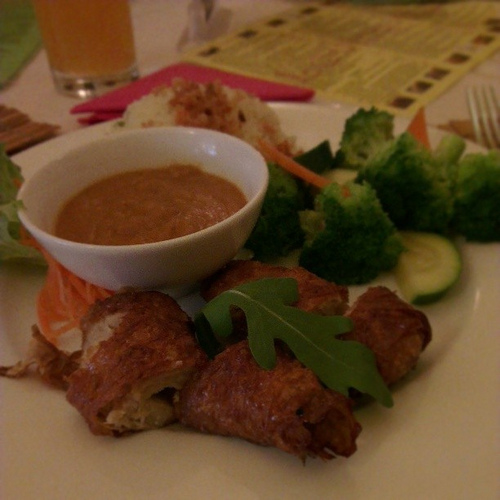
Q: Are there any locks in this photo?
A: No, there are no locks.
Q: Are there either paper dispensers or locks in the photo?
A: No, there are no locks or paper dispensers.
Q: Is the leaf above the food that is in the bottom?
A: Yes, the leaf is above the food.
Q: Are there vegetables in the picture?
A: Yes, there are vegetables.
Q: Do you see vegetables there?
A: Yes, there are vegetables.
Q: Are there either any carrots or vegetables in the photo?
A: Yes, there are vegetables.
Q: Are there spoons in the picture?
A: No, there are no spoons.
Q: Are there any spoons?
A: No, there are no spoons.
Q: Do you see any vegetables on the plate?
A: Yes, there are vegetables on the plate.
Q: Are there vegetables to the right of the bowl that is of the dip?
A: Yes, there are vegetables to the right of the bowl.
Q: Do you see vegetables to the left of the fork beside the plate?
A: Yes, there are vegetables to the left of the fork.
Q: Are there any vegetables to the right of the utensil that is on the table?
A: No, the vegetables are to the left of the fork.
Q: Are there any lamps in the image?
A: No, there are no lamps.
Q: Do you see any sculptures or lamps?
A: No, there are no lamps or sculptures.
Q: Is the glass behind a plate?
A: Yes, the glass is behind a plate.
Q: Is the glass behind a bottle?
A: No, the glass is behind a plate.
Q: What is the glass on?
A: The glass is on the table.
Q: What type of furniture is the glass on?
A: The glass is on the table.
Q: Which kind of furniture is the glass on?
A: The glass is on the table.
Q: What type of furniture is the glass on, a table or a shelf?
A: The glass is on a table.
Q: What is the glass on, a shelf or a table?
A: The glass is on a table.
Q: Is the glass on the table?
A: Yes, the glass is on the table.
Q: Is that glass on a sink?
A: No, the glass is on the table.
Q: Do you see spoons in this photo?
A: No, there are no spoons.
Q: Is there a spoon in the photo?
A: No, there are no spoons.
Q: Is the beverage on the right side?
A: No, the beverage is on the left of the image.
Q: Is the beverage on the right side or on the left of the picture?
A: The beverage is on the left of the image.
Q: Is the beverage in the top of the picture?
A: Yes, the beverage is in the top of the image.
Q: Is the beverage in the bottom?
A: No, the beverage is in the top of the image.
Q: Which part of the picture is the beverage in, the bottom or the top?
A: The beverage is in the top of the image.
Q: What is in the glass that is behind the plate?
A: The beverage is in the glass.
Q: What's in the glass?
A: The beverage is in the glass.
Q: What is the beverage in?
A: The beverage is in the glass.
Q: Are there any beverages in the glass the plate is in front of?
A: Yes, there is a beverage in the glass.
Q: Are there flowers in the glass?
A: No, there is a beverage in the glass.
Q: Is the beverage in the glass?
A: Yes, the beverage is in the glass.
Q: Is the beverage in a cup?
A: No, the beverage is in the glass.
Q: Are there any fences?
A: No, there are no fences.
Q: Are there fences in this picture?
A: No, there are no fences.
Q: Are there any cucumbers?
A: Yes, there is a cucumber.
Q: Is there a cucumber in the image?
A: Yes, there is a cucumber.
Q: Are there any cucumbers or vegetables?
A: Yes, there is a cucumber.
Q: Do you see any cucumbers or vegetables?
A: Yes, there is a cucumber.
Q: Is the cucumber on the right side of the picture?
A: Yes, the cucumber is on the right of the image.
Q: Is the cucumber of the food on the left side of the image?
A: No, the cucumber is on the right of the image.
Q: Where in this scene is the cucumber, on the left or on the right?
A: The cucumber is on the right of the image.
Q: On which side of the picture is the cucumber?
A: The cucumber is on the right of the image.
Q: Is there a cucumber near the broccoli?
A: Yes, there is a cucumber near the broccoli.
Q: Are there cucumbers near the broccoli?
A: Yes, there is a cucumber near the broccoli.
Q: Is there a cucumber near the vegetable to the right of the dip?
A: Yes, there is a cucumber near the broccoli.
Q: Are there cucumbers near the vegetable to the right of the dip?
A: Yes, there is a cucumber near the broccoli.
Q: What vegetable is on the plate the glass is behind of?
A: The vegetable is a cucumber.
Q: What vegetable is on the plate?
A: The vegetable is a cucumber.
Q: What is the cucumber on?
A: The cucumber is on the plate.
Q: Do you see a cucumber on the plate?
A: Yes, there is a cucumber on the plate.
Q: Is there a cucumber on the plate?
A: Yes, there is a cucumber on the plate.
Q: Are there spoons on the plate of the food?
A: No, there is a cucumber on the plate.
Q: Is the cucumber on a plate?
A: Yes, the cucumber is on a plate.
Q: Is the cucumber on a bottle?
A: No, the cucumber is on a plate.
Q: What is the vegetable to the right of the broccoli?
A: The vegetable is a cucumber.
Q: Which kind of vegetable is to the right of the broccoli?
A: The vegetable is a cucumber.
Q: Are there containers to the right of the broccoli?
A: No, there is a cucumber to the right of the broccoli.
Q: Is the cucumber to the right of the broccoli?
A: Yes, the cucumber is to the right of the broccoli.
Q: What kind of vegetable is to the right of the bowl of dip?
A: The vegetable is a cucumber.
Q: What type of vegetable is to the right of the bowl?
A: The vegetable is a cucumber.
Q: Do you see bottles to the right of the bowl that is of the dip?
A: No, there is a cucumber to the right of the bowl.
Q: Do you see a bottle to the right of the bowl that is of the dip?
A: No, there is a cucumber to the right of the bowl.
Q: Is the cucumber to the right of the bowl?
A: Yes, the cucumber is to the right of the bowl.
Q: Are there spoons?
A: No, there are no spoons.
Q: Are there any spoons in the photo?
A: No, there are no spoons.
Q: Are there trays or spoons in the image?
A: No, there are no spoons or trays.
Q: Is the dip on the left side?
A: Yes, the dip is on the left of the image.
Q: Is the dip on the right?
A: No, the dip is on the left of the image.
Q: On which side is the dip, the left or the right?
A: The dip is on the left of the image.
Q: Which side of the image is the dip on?
A: The dip is on the left of the image.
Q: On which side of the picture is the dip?
A: The dip is on the left of the image.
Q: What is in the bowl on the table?
A: The dip is in the bowl.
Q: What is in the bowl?
A: The dip is in the bowl.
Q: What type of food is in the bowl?
A: The food is a dip.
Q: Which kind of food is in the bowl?
A: The food is a dip.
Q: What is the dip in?
A: The dip is in the bowl.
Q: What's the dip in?
A: The dip is in the bowl.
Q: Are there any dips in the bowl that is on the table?
A: Yes, there is a dip in the bowl.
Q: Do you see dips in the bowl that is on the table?
A: Yes, there is a dip in the bowl.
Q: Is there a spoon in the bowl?
A: No, there is a dip in the bowl.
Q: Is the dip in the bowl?
A: Yes, the dip is in the bowl.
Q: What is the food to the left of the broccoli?
A: The food is a dip.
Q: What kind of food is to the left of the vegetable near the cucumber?
A: The food is a dip.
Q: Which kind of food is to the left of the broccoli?
A: The food is a dip.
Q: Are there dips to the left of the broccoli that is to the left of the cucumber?
A: Yes, there is a dip to the left of the broccoli.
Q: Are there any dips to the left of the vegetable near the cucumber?
A: Yes, there is a dip to the left of the broccoli.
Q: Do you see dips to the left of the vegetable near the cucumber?
A: Yes, there is a dip to the left of the broccoli.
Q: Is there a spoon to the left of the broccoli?
A: No, there is a dip to the left of the broccoli.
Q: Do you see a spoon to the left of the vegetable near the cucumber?
A: No, there is a dip to the left of the broccoli.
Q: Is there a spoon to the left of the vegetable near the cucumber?
A: No, there is a dip to the left of the broccoli.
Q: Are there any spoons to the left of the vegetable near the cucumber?
A: No, there is a dip to the left of the broccoli.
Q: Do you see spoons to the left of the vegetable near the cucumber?
A: No, there is a dip to the left of the broccoli.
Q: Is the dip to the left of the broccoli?
A: Yes, the dip is to the left of the broccoli.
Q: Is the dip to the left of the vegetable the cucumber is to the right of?
A: Yes, the dip is to the left of the broccoli.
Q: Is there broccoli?
A: Yes, there is broccoli.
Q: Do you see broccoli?
A: Yes, there is broccoli.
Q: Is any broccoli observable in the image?
A: Yes, there is broccoli.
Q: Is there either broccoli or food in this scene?
A: Yes, there is broccoli.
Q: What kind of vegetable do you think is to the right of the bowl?
A: The vegetable is broccoli.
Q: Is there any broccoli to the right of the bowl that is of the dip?
A: Yes, there is broccoli to the right of the bowl.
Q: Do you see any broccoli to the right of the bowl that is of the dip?
A: Yes, there is broccoli to the right of the bowl.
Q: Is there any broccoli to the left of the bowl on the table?
A: No, the broccoli is to the right of the bowl.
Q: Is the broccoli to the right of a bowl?
A: Yes, the broccoli is to the right of a bowl.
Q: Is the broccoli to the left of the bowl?
A: No, the broccoli is to the right of the bowl.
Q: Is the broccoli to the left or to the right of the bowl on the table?
A: The broccoli is to the right of the bowl.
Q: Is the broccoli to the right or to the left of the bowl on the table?
A: The broccoli is to the right of the bowl.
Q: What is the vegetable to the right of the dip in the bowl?
A: The vegetable is broccoli.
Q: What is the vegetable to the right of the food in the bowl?
A: The vegetable is broccoli.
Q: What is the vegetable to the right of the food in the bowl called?
A: The vegetable is broccoli.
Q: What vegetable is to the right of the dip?
A: The vegetable is broccoli.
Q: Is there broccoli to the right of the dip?
A: Yes, there is broccoli to the right of the dip.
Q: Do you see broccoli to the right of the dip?
A: Yes, there is broccoli to the right of the dip.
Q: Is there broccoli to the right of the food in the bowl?
A: Yes, there is broccoli to the right of the dip.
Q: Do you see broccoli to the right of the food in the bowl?
A: Yes, there is broccoli to the right of the dip.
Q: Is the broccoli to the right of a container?
A: No, the broccoli is to the right of the dip.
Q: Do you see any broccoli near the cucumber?
A: Yes, there is broccoli near the cucumber.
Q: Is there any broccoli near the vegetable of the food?
A: Yes, there is broccoli near the cucumber.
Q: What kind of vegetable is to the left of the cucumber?
A: The vegetable is broccoli.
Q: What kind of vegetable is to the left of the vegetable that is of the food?
A: The vegetable is broccoli.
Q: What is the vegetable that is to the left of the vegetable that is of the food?
A: The vegetable is broccoli.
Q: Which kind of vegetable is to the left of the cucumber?
A: The vegetable is broccoli.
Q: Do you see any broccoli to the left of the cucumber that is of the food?
A: Yes, there is broccoli to the left of the cucumber.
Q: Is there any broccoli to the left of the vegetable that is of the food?
A: Yes, there is broccoli to the left of the cucumber.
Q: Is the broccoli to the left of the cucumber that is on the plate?
A: Yes, the broccoli is to the left of the cucumber.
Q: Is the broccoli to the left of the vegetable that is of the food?
A: Yes, the broccoli is to the left of the cucumber.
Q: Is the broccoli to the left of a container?
A: No, the broccoli is to the left of the cucumber.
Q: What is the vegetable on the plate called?
A: The vegetable is broccoli.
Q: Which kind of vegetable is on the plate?
A: The vegetable is broccoli.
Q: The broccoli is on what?
A: The broccoli is on the plate.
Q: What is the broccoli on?
A: The broccoli is on the plate.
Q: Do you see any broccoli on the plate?
A: Yes, there is broccoli on the plate.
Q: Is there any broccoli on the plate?
A: Yes, there is broccoli on the plate.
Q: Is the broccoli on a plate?
A: Yes, the broccoli is on a plate.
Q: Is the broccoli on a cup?
A: No, the broccoli is on a plate.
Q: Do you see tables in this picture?
A: Yes, there is a table.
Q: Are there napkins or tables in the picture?
A: Yes, there is a table.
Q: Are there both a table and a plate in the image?
A: Yes, there are both a table and a plate.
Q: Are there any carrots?
A: Yes, there are carrots.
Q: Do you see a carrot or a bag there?
A: Yes, there are carrots.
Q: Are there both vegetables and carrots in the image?
A: Yes, there are both carrots and vegetables.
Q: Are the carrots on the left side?
A: Yes, the carrots are on the left of the image.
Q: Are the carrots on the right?
A: No, the carrots are on the left of the image.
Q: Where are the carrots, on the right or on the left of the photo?
A: The carrots are on the left of the image.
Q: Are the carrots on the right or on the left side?
A: The carrots are on the left of the image.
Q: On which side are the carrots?
A: The carrots are on the left of the image.